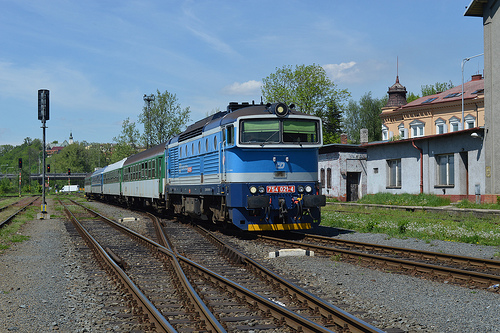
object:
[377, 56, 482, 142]
building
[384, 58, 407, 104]
tower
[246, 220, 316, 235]
trim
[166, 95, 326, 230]
blue engine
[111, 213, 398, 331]
gravel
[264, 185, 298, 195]
red license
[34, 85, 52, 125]
signal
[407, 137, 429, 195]
gutter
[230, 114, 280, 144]
window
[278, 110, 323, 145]
window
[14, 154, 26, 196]
stop light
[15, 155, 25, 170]
traffic light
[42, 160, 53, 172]
traffic light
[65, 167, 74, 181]
traffic light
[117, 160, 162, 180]
windows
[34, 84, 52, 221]
light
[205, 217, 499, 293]
tracks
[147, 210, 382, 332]
tracks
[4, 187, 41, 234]
tracks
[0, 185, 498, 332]
tracks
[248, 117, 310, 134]
shades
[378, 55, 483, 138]
yellow building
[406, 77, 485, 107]
red roof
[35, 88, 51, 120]
light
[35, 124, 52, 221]
pole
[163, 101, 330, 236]
engine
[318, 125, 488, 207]
building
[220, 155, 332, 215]
lights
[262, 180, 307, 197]
letters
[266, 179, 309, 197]
numbers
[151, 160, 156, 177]
window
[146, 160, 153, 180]
window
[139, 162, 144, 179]
window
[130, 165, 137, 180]
window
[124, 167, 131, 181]
window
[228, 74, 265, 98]
clouds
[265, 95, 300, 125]
head light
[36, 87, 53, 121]
traffic light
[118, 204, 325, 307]
tracks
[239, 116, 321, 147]
front window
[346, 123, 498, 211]
building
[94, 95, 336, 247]
train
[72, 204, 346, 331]
tracks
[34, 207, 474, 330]
tracks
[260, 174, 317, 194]
plate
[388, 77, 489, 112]
roof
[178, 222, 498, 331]
tracks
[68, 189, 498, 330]
train tracks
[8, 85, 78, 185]
lights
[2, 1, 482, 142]
sky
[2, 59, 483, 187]
background